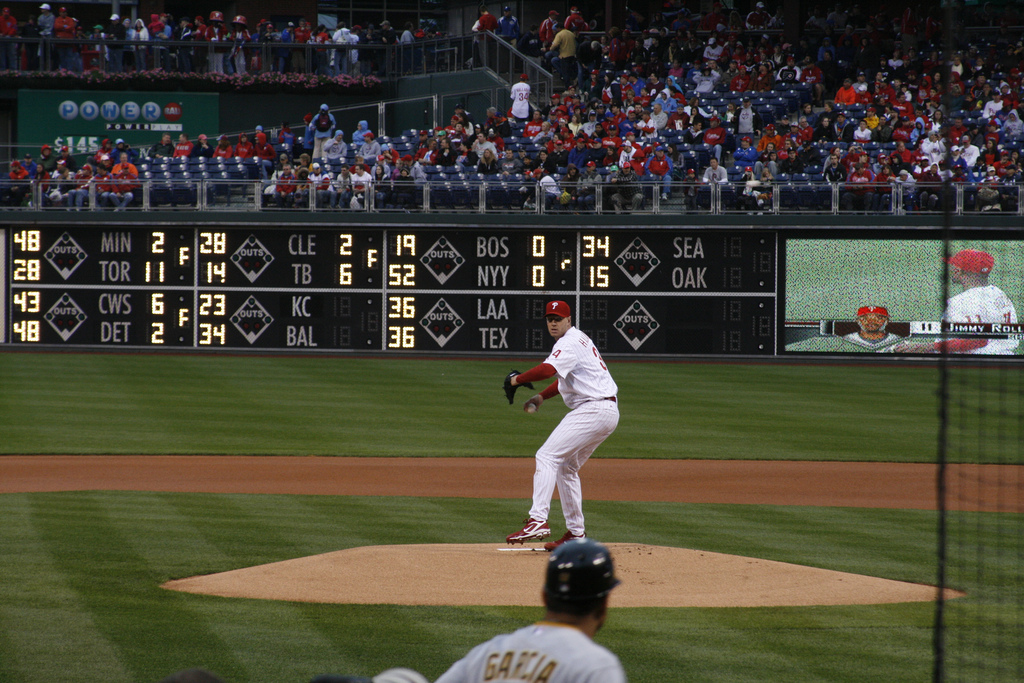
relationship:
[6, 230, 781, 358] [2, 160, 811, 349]
scoreboard on fence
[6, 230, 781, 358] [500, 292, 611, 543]
scoreboard behind pitcher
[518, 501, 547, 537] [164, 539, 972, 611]
foot off mound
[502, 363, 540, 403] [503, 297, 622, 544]
glove on pitcher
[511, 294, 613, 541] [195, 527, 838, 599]
pitcher on mound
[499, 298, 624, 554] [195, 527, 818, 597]
pitcher baseball pitchers mound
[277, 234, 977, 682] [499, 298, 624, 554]
two opposing baseball pitcher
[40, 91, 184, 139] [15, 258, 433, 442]
lottery advertisement on wall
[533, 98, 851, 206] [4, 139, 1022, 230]
fans sitting in stands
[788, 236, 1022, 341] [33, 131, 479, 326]
television screen against back wall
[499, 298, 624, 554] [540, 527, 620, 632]
pitcher wearing a helmet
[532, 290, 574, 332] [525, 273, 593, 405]
hat on pitchers head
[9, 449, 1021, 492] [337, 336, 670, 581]
basepath behind pitcher